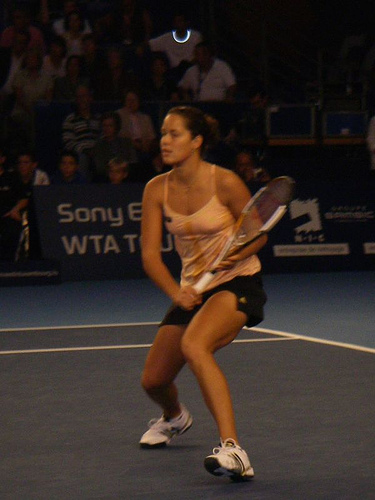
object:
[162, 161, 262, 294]
tennis shirt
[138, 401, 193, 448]
shoe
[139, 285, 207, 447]
leg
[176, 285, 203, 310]
hand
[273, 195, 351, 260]
sponsor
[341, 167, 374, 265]
wall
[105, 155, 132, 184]
spectator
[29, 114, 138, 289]
stand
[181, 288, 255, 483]
leg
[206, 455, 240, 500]
raised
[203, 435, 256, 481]
shoe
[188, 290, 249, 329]
skirt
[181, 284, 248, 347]
thigh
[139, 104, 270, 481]
player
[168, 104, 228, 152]
hair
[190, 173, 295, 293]
tennis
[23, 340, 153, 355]
line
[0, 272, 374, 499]
court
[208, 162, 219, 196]
strap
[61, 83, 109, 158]
people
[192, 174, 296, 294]
racket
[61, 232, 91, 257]
words